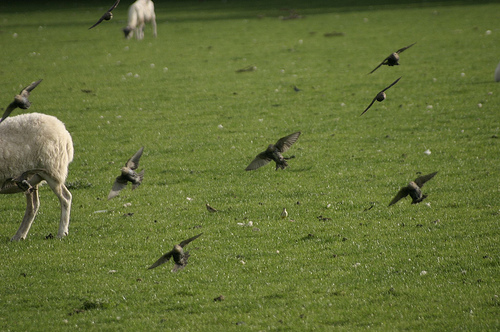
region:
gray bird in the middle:
[226, 117, 318, 189]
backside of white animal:
[0, 109, 83, 250]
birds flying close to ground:
[120, 109, 436, 253]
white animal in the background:
[108, 0, 216, 62]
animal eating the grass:
[117, 11, 177, 48]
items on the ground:
[211, 196, 389, 306]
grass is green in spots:
[150, 91, 251, 221]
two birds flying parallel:
[355, 35, 426, 138]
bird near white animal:
[0, 85, 55, 128]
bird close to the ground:
[156, 230, 215, 295]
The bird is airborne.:
[82, 0, 129, 35]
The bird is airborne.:
[0, 65, 50, 130]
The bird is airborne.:
[106, 138, 163, 208]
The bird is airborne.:
[126, 228, 253, 285]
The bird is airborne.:
[227, 108, 320, 200]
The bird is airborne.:
[353, 71, 464, 124]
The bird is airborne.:
[369, 150, 462, 224]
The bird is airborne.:
[343, 29, 433, 84]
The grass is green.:
[2, 4, 497, 329]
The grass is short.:
[1, 2, 499, 329]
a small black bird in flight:
[150, 230, 202, 274]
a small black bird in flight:
[248, 132, 300, 174]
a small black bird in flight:
[390, 170, 440, 206]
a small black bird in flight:
[362, 77, 398, 114]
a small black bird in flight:
[370, 41, 415, 77]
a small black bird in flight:
[105, 145, 145, 195]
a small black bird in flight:
[2, 77, 44, 120]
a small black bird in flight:
[87, 0, 121, 28]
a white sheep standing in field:
[0, 110, 75, 238]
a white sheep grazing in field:
[120, 1, 157, 39]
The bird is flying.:
[0, 66, 51, 123]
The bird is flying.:
[82, 0, 134, 35]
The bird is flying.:
[101, 133, 166, 215]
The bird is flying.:
[146, 225, 231, 285]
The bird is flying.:
[240, 113, 313, 187]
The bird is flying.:
[379, 143, 449, 226]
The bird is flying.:
[357, 65, 409, 136]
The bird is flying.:
[348, 25, 439, 82]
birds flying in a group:
[78, 52, 495, 319]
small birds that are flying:
[101, 100, 472, 315]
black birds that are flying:
[94, 61, 439, 318]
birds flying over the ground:
[107, 40, 472, 261]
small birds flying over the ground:
[14, 62, 496, 292]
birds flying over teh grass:
[32, 63, 492, 321]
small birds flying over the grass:
[46, 54, 497, 326]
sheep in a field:
[16, 36, 376, 268]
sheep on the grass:
[15, 37, 283, 328]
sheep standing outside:
[22, 59, 276, 324]